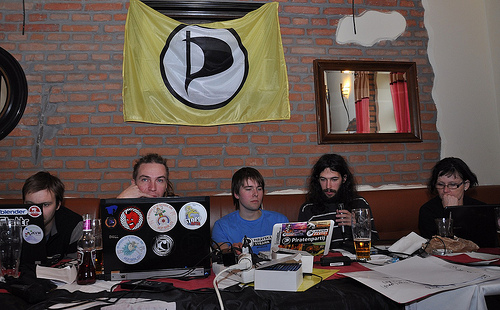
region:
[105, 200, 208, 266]
stickers on laptop lid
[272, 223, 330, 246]
stickers on laptop lid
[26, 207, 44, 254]
stickers on laptop lid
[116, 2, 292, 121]
yellow, black and white flag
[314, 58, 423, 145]
mirror with brown frame on wall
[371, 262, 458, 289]
white paper ton table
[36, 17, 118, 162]
red and gray brick wall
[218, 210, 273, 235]
young man wearing blue and white shirt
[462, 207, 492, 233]
young woman wearing black shirt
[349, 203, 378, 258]
clear glass of tan beer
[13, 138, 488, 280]
five people sitting in a booth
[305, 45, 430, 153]
a mirror with wood frame hanging on the wall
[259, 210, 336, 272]
a small white laptop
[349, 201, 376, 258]
a tall glass with beer in it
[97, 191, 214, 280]
a black laptop with stickers on it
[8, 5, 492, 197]
a wall painted to look like bricks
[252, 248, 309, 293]
a white box with the top open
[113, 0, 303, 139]
a yellow flag covering the window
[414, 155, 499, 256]
a lady in glasses and long sleeve black shirt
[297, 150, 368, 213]
a long hair man with a beard and mustache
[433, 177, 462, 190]
The black eyeglasses the lady is wearing.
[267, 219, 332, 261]
The small white laptop in front of the guy in the blue t-shirt.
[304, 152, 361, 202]
The head of the guy with long hair and a mustache.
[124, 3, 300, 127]
The yellow flag hanging on the brick wall.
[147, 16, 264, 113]
The black and white design on the yellow flag.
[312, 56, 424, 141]
The brown framed mirror on the brick wall.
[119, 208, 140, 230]
The devil sticker on the black laptop.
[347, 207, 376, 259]
The tall glass in front of the guy with long hair.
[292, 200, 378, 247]
The striped shirt worn by the guy with long hair.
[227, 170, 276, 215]
The head of the guy in the light blue t-shirt.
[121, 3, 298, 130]
the sign is yellow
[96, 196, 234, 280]
the laptop has logos on it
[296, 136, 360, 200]
the man has black curly hair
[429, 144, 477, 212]
the person is wearing glasses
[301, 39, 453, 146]
a mirror is on the wall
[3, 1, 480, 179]
the wall is made of brick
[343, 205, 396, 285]
a glass cup is on the table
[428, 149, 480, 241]
the woman's hand is on her face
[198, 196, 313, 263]
the man's shirt is blue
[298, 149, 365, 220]
the man has a beard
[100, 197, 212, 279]
A laptop with many stickers on it.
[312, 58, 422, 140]
A framed mirror on the wall.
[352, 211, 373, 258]
A 1/3 full glass of beer.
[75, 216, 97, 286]
An open bottle of alcohol.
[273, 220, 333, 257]
A small laptop with large stickers on it.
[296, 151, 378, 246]
A man with long hair holding a microphone.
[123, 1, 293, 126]
A yellow flag with a logo emblazoned upon it.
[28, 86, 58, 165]
A crack in the brick wall.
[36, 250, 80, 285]
A book sitting between two laptops.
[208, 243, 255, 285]
A surge protector with several things plugged in.